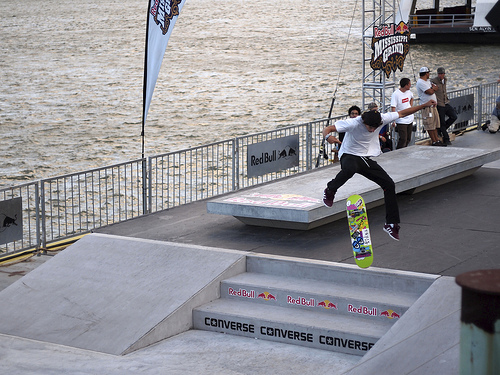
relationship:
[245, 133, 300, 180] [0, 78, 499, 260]
banner in fence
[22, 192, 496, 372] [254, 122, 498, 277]
skate park on a pier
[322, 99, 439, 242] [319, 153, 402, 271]
boy doing a skateboarding trick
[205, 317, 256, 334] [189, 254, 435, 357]
converse on stairs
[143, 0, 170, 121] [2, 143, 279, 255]
flag attached to gates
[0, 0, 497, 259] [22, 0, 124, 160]
river filled with water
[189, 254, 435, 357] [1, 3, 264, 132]
stairs near river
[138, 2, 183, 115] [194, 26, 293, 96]
blue flag near river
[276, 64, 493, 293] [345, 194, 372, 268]
boy doing a skateboard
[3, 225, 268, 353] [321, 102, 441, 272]
ramp used for skateboarding tricks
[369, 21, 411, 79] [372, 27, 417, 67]
mississippi grand for mississippi grand